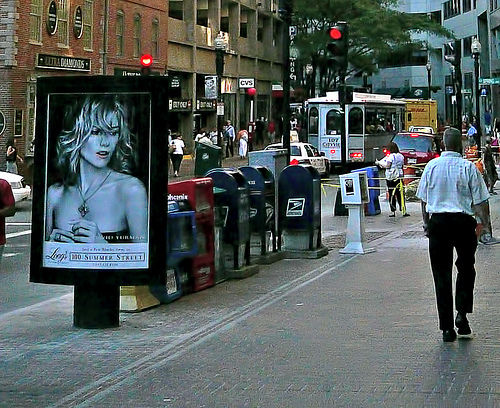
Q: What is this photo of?
A: A street.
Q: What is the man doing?
A: Walking.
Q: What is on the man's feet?
A: Shoes.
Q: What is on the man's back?
A: A shirt.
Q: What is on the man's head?
A: His hair.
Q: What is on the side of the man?
A: Mailboxes.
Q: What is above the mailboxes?
A: A stop light.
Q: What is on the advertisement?
A: Female model.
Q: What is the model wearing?
A: Necklace.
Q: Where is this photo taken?
A: Busy street.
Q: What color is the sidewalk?
A: Brown.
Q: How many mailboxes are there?
A: Three.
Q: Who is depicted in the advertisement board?
A: Blonde woman.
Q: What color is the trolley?
A: White.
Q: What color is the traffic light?
A: Red.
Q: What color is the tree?
A: Green.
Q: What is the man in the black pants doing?
A: Walking.